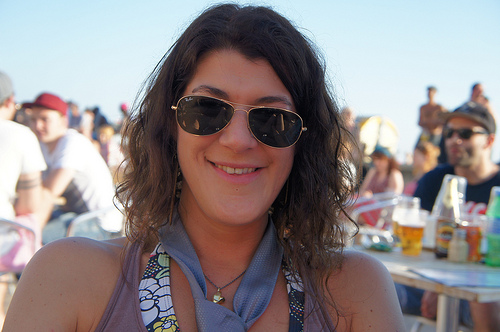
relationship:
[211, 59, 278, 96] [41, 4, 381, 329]
head of woman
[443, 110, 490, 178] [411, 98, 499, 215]
head of person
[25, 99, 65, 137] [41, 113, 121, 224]
head of person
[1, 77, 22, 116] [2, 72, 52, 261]
head of person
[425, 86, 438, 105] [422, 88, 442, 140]
head of person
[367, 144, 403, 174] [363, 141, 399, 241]
head of person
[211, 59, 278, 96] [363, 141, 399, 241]
head of person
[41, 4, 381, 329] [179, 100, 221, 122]
woman wearing sunglasses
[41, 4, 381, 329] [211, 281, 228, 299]
woman with necklace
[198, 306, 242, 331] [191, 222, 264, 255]
tie around neck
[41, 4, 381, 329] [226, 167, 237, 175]
woman has tooth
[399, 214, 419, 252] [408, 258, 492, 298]
cup on table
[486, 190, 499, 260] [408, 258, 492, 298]
bottle on table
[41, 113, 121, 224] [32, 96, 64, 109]
person wearing cap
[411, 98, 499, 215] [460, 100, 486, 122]
person wearing cap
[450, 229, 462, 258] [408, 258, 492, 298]
condiment on table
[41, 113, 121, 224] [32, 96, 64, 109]
person has cap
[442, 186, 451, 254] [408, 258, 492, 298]
bottle on table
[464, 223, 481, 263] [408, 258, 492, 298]
drink on table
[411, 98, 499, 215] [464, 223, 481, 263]
person near drink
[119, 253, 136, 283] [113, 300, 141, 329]
strap on top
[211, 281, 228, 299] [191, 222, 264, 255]
necklace around neck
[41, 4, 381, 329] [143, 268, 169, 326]
woman wearing swimsuit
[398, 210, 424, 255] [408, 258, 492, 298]
cup on table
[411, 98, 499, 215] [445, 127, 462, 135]
person has sunglasses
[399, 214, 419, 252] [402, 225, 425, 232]
cup has beer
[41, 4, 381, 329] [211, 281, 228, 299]
woman wearing necklace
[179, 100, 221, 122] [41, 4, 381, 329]
sunglasses on woman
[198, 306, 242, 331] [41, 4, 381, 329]
tie on woman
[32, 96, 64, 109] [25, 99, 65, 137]
cap on head